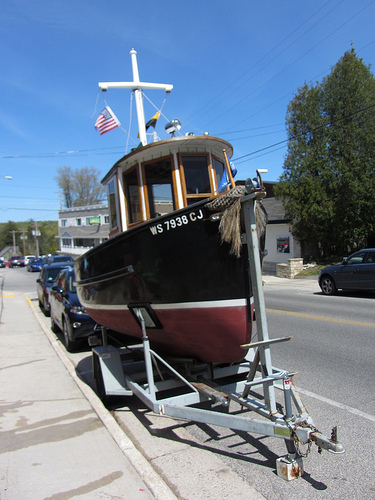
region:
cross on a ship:
[108, 35, 189, 119]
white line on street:
[306, 385, 344, 423]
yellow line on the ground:
[298, 303, 337, 338]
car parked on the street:
[312, 234, 372, 276]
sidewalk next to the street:
[10, 341, 59, 394]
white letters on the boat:
[134, 201, 222, 254]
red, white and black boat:
[167, 271, 246, 342]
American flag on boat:
[97, 102, 136, 134]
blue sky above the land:
[38, 11, 97, 68]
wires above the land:
[17, 140, 74, 222]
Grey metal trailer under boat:
[103, 338, 324, 473]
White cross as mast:
[98, 30, 201, 145]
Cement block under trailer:
[271, 460, 305, 483]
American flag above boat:
[84, 95, 128, 141]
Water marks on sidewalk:
[3, 402, 98, 443]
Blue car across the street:
[304, 237, 369, 282]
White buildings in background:
[57, 196, 309, 275]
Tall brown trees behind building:
[51, 160, 130, 218]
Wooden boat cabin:
[109, 150, 238, 213]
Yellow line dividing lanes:
[269, 302, 371, 337]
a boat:
[83, 252, 271, 410]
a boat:
[49, 183, 202, 367]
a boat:
[102, 258, 216, 383]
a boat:
[62, 199, 325, 487]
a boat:
[53, 255, 174, 418]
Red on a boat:
[67, 281, 299, 384]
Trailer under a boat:
[80, 312, 374, 495]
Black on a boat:
[63, 203, 271, 317]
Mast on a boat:
[72, 35, 190, 161]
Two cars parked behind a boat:
[25, 244, 134, 353]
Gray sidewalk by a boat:
[0, 321, 154, 498]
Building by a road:
[48, 194, 137, 262]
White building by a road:
[242, 187, 344, 286]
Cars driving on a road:
[6, 247, 59, 277]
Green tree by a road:
[280, 41, 372, 285]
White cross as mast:
[97, 48, 170, 133]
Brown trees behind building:
[57, 162, 107, 195]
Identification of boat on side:
[144, 199, 217, 246]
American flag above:
[105, 111, 117, 128]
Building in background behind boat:
[56, 206, 300, 272]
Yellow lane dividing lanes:
[269, 300, 369, 324]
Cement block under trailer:
[270, 453, 311, 474]